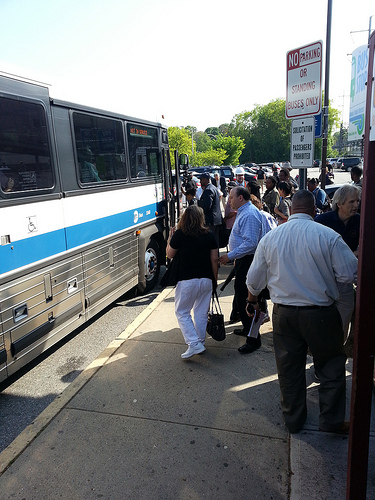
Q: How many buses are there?
A: One.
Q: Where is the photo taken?
A: On a sidewalk.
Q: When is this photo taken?
A: Daytime.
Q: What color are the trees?
A: Green.